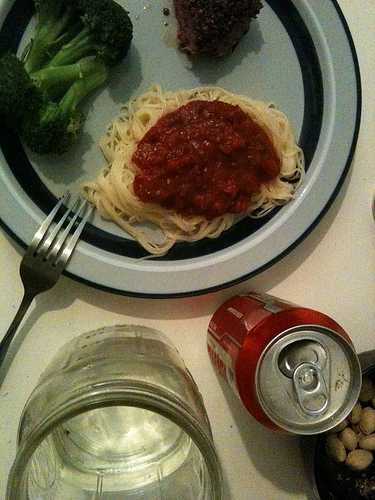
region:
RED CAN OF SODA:
[205, 288, 364, 438]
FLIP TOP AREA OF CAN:
[274, 339, 339, 416]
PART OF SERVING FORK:
[12, 192, 95, 291]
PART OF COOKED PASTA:
[130, 103, 162, 127]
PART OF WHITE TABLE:
[300, 267, 340, 309]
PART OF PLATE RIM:
[294, 103, 308, 140]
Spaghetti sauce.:
[135, 98, 279, 219]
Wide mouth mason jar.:
[6, 323, 222, 498]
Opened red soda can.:
[207, 290, 362, 436]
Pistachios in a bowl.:
[313, 440, 371, 497]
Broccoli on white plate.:
[0, 48, 91, 162]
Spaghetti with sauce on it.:
[85, 85, 302, 254]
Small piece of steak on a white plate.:
[173, 0, 260, 62]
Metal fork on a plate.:
[2, 190, 92, 389]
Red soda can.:
[204, 289, 359, 432]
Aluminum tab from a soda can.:
[294, 364, 332, 416]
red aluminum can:
[200, 297, 352, 436]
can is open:
[235, 299, 350, 439]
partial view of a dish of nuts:
[335, 406, 370, 485]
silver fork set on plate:
[0, 228, 100, 337]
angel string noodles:
[106, 100, 140, 223]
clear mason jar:
[51, 338, 194, 498]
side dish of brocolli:
[19, 21, 124, 124]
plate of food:
[4, 15, 347, 253]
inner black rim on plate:
[280, 42, 329, 143]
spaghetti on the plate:
[113, 86, 279, 263]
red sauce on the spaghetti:
[165, 114, 252, 194]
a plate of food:
[0, 2, 367, 291]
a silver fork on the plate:
[14, 191, 105, 298]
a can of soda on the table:
[214, 295, 354, 445]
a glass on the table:
[26, 345, 210, 494]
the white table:
[325, 255, 373, 306]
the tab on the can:
[299, 364, 329, 410]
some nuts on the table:
[323, 402, 371, 450]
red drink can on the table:
[201, 292, 355, 441]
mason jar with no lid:
[13, 325, 213, 498]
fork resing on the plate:
[0, 189, 108, 361]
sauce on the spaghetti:
[134, 104, 278, 221]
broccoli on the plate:
[9, 4, 125, 143]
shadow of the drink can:
[218, 372, 317, 498]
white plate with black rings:
[1, 2, 363, 290]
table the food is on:
[6, 14, 370, 455]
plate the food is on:
[2, 2, 357, 288]